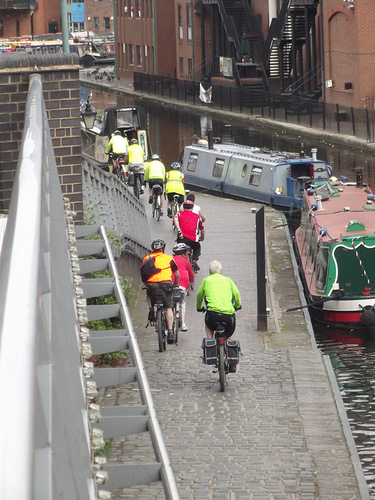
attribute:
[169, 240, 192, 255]
helmet — black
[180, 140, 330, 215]
boat — blue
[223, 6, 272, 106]
staircase — iron, black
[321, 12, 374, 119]
building — red, brick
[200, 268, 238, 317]
jacket — lime green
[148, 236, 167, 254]
helmet — black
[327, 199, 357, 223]
roof — pink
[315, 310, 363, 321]
stripe — red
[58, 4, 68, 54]
pole — green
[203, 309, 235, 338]
shorts — black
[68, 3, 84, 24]
sign — blue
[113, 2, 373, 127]
building — red, brick